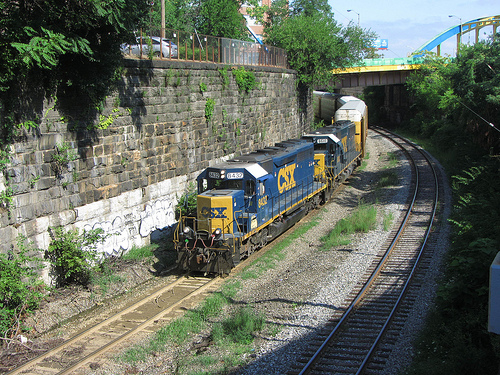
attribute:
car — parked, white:
[122, 39, 173, 59]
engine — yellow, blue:
[166, 137, 323, 274]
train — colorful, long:
[162, 83, 375, 283]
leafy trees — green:
[403, 32, 498, 110]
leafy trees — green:
[243, 0, 380, 93]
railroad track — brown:
[401, 190, 425, 279]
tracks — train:
[335, 137, 455, 372]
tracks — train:
[23, 283, 208, 373]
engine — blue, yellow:
[141, 60, 404, 267]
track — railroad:
[298, 128, 465, 370]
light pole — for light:
[448, 12, 467, 48]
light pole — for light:
[345, 9, 365, 49]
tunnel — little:
[328, 87, 418, 135]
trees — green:
[413, 60, 497, 117]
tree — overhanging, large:
[0, 0, 152, 102]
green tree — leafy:
[4, 0, 157, 135]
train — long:
[174, 93, 369, 272]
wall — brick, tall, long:
[138, 58, 260, 143]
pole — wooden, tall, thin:
[146, 13, 181, 33]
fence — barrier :
[130, 22, 289, 70]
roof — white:
[333, 89, 367, 131]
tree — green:
[1, 0, 153, 69]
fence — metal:
[127, 25, 319, 86]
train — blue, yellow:
[193, 148, 340, 209]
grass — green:
[201, 310, 260, 350]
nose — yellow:
[201, 190, 231, 238]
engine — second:
[305, 116, 358, 188]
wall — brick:
[6, 51, 304, 296]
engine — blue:
[179, 140, 319, 270]